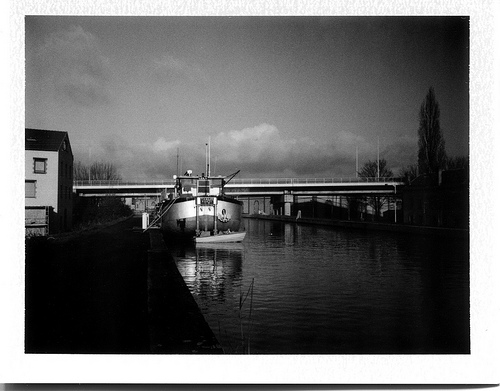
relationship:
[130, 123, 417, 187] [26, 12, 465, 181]
clouds in sky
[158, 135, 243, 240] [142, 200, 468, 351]
boat on water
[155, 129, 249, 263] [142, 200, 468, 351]
boat parked in water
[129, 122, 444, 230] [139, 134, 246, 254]
bridge behind boat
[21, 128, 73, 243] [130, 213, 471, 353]
house near water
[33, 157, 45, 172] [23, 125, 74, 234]
window in house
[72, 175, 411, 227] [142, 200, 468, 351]
bridge over water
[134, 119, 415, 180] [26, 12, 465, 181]
clouds in sky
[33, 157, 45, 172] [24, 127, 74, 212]
window on house